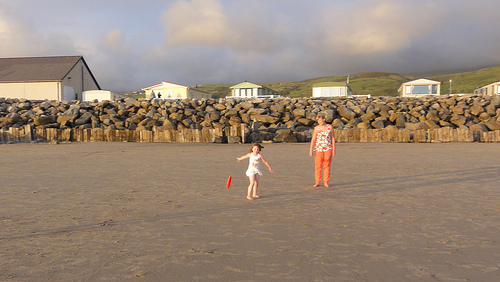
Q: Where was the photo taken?
A: At the beach.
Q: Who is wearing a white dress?
A: Little girl.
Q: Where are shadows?
A: On the sand.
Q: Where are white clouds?
A: In the sky.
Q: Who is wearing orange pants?
A: The woman.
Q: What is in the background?
A: Houses.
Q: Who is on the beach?
A: A woman and a girl.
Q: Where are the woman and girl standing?
A: In the sand.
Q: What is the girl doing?
A: Throwing a Frisbee.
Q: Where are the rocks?
A: At the edge of the sand.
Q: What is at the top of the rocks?
A: Houses.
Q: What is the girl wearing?
A: A white dress.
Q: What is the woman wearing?
A: Orange pants and a sleeveless floral shirt.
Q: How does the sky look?
A: Cloudy.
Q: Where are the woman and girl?
A: At the beach.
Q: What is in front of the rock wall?
A: A wooden fence.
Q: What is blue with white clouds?
A: Sky.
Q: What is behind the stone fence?
A: Homes.